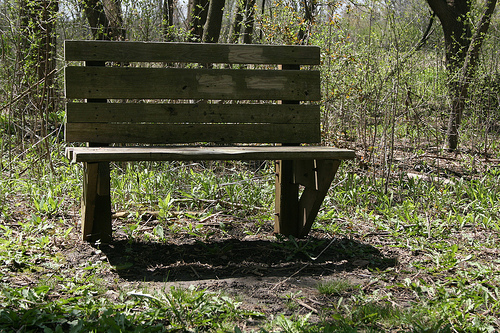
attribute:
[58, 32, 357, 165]
bench — wood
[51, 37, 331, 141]
planks — wood, uneven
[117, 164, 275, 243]
plants — green, leafy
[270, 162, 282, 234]
bolts — silver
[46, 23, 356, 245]
bench — brown, in the foreground, wooden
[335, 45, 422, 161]
plants — thin, Brown, stalks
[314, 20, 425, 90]
leaves — green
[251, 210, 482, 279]
sticks — brown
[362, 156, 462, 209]
plants — smaller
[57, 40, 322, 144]
planks — worn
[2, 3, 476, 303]
photo — outdoors, daytime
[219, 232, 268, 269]
shadow — dark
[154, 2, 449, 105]
trees — green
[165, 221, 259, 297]
patch — brown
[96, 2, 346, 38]
sky — blue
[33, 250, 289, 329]
plants — green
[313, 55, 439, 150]
plants — green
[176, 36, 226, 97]
gap — small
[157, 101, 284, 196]
bench — old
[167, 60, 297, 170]
bench — old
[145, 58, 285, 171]
bench — brown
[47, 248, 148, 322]
grass — green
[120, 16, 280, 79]
wood — brown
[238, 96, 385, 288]
shadow — dark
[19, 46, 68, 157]
leaves — green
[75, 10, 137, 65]
sky — white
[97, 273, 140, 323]
grass — green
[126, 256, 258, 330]
ground — brown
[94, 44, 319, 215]
chair — old